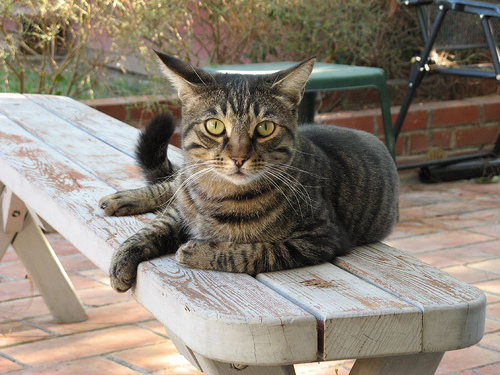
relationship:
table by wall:
[190, 57, 400, 166] [282, 95, 483, 177]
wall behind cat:
[328, 100, 498, 162] [88, 53, 401, 294]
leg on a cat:
[104, 212, 173, 294] [127, 24, 407, 321]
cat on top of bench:
[97, 47, 403, 294] [18, 82, 488, 372]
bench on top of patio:
[18, 82, 488, 372] [23, 126, 494, 373]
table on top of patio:
[190, 57, 400, 166] [4, 156, 497, 373]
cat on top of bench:
[128, 41, 403, 272] [18, 82, 488, 372]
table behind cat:
[182, 44, 385, 103] [128, 41, 403, 272]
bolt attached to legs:
[5, 199, 28, 226] [5, 188, 84, 321]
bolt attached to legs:
[220, 341, 260, 372] [203, 346, 459, 365]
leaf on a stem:
[53, 71, 71, 82] [36, 3, 117, 89]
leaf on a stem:
[209, 1, 228, 18] [96, 0, 194, 54]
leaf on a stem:
[72, 75, 101, 96] [70, 36, 139, 98]